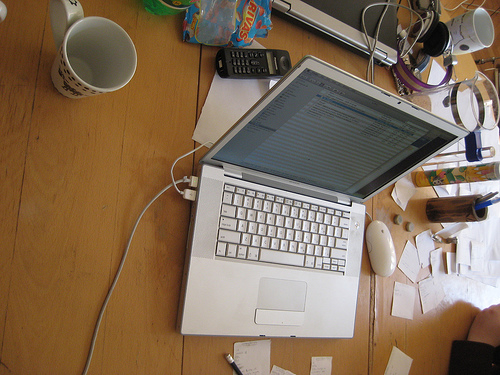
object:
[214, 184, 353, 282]
keyboard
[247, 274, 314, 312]
trackpad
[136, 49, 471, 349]
laptop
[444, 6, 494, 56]
cup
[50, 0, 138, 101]
cup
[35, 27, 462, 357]
desk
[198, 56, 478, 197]
screen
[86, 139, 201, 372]
cords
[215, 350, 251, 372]
pencil